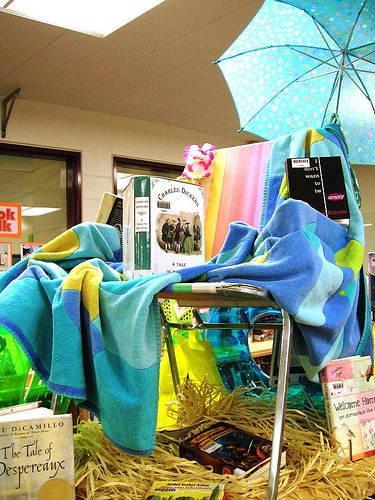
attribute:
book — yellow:
[145, 475, 228, 499]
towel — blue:
[0, 122, 374, 455]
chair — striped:
[140, 122, 359, 488]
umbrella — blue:
[198, 5, 373, 197]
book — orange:
[317, 352, 371, 467]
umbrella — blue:
[210, 1, 373, 167]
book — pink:
[157, 385, 295, 488]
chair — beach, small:
[99, 124, 356, 496]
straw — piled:
[144, 407, 323, 494]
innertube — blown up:
[203, 304, 324, 418]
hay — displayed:
[72, 376, 373, 499]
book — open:
[0, 395, 82, 498]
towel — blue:
[84, 285, 153, 442]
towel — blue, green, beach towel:
[187, 169, 319, 282]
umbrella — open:
[195, 26, 361, 201]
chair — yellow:
[61, 120, 351, 470]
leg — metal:
[269, 305, 289, 498]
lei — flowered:
[170, 132, 216, 193]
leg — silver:
[265, 307, 297, 499]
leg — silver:
[159, 306, 187, 412]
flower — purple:
[182, 141, 215, 177]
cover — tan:
[0, 397, 74, 497]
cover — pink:
[321, 354, 372, 457]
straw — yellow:
[71, 373, 373, 499]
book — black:
[285, 157, 353, 235]